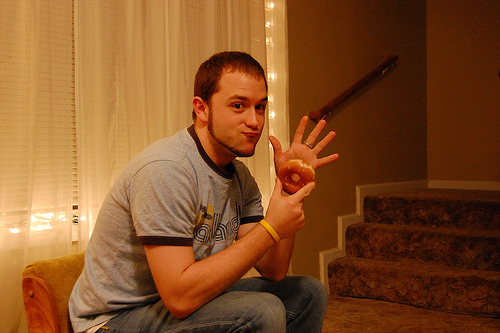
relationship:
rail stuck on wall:
[310, 55, 397, 120] [288, 2, 499, 191]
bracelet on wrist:
[260, 220, 280, 244] [257, 215, 284, 250]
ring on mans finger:
[302, 140, 312, 148] [308, 118, 325, 145]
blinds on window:
[71, 1, 77, 209] [1, 1, 87, 254]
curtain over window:
[1, 1, 71, 256] [1, 1, 87, 254]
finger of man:
[313, 131, 335, 153] [68, 51, 341, 332]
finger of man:
[316, 152, 339, 167] [68, 51, 341, 332]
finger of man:
[294, 114, 310, 142] [68, 51, 341, 332]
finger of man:
[268, 136, 283, 153] [68, 51, 341, 332]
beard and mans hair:
[207, 102, 214, 137] [190, 52, 228, 121]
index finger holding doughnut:
[291, 181, 314, 202] [277, 160, 315, 194]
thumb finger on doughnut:
[273, 177, 282, 196] [277, 160, 315, 194]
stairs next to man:
[328, 194, 500, 320] [68, 51, 341, 332]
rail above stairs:
[310, 55, 397, 120] [328, 194, 500, 320]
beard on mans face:
[207, 102, 214, 137] [213, 74, 266, 157]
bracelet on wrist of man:
[260, 220, 280, 244] [68, 51, 341, 332]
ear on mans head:
[194, 96, 206, 120] [191, 52, 268, 157]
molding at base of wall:
[427, 177, 499, 190] [288, 2, 499, 191]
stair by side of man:
[329, 257, 499, 317] [68, 51, 341, 332]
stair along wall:
[365, 196, 500, 228] [288, 2, 499, 191]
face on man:
[213, 74, 266, 157] [68, 51, 341, 332]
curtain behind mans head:
[1, 1, 71, 256] [191, 52, 268, 157]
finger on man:
[268, 136, 283, 153] [68, 51, 341, 332]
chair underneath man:
[23, 250, 87, 333] [68, 51, 341, 332]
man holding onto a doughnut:
[68, 51, 341, 332] [277, 160, 315, 194]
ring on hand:
[302, 140, 312, 148] [270, 116, 338, 177]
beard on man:
[207, 102, 214, 137] [68, 51, 341, 332]